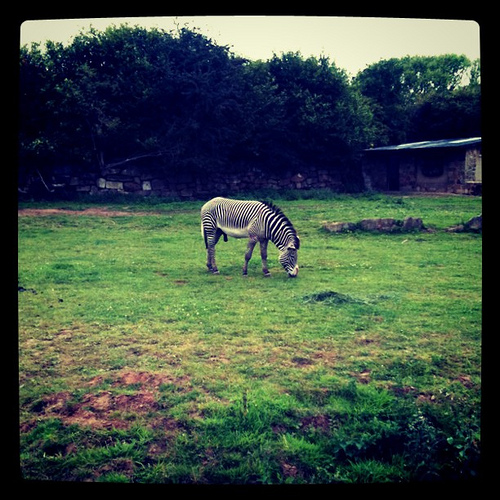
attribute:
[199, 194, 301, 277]
zebra — black, striped, white, alone, eating, grazing, four-legged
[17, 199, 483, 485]
grass — green, brown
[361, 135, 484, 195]
building — brown, small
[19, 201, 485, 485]
field — grassy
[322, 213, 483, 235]
rocks — large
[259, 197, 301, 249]
mane — black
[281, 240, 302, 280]
head — down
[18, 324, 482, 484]
patches — brown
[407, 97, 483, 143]
tree — green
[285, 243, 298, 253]
ear — black, white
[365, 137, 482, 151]
roof — blue